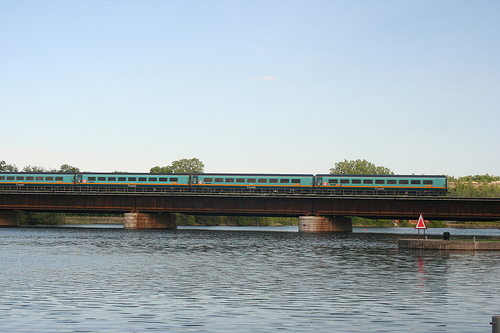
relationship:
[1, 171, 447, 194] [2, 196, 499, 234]
train on bridge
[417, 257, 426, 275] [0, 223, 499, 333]
reflection on water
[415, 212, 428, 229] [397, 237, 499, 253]
sign on platform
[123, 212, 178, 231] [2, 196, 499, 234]
pillar holding up bridge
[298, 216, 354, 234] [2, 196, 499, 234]
pillar holding up bridge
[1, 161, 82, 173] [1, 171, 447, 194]
trees are behind train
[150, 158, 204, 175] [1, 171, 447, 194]
trees are behind train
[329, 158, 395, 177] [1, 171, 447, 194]
trees are behind train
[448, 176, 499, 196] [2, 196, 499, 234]
hill behind bridge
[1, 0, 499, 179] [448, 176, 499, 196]
sky above hill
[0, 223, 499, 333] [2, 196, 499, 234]
water passing under bridge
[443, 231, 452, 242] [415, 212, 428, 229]
object next to sign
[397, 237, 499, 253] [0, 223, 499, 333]
platform in water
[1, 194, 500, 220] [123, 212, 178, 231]
train track perched on pillar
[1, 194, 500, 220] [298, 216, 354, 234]
train track perched on pillar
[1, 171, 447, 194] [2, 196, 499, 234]
train crossing bridge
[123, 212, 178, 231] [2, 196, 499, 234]
pillar supports bridge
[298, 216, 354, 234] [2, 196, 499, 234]
pillar supports bridge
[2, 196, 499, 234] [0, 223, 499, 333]
bridge over water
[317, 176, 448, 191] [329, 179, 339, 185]
train car has window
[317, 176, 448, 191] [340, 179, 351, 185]
train car has window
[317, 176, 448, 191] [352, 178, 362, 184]
train car has window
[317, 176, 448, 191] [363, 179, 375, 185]
train car has window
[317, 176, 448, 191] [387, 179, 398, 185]
train car has window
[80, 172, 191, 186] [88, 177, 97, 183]
train car has window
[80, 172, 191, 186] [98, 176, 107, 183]
train car has window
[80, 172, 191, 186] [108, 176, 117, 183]
train car has window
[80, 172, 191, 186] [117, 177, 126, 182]
train car has window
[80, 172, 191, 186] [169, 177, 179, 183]
train car has window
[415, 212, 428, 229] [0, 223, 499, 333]
sign in water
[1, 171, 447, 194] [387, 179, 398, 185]
train has window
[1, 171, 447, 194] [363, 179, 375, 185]
train has window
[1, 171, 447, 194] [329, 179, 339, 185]
train has window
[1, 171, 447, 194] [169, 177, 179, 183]
train has window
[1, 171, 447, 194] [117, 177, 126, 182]
train has window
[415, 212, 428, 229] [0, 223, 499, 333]
sign in middle of water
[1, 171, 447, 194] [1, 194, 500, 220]
train on train track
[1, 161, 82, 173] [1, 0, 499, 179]
trees are against sky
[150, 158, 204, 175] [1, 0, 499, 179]
trees are against sky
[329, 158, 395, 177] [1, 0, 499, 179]
trees are against sky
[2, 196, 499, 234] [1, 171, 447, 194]
bridge for train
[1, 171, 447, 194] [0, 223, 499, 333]
train traveling over water